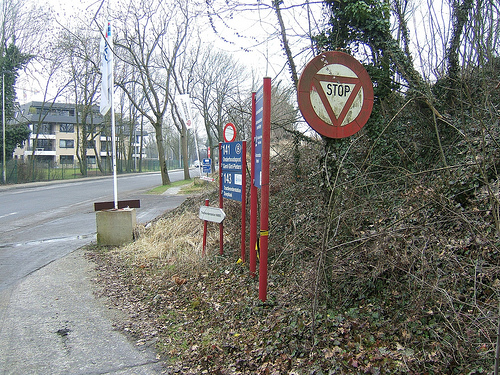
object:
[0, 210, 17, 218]
marking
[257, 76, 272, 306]
pole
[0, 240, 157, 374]
sidewalk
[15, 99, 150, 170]
building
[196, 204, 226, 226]
sign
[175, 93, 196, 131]
banner flag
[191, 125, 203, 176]
pole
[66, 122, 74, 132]
small window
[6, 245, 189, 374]
shoulder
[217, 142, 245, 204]
board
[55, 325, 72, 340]
mark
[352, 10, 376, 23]
green leaves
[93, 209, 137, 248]
cement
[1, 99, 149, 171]
building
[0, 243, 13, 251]
puddle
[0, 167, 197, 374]
pavement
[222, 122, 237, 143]
red sign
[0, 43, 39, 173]
trees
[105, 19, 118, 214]
flag pole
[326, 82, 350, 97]
word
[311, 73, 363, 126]
triangle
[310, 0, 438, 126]
tree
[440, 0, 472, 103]
tree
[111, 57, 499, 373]
hill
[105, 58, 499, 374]
grass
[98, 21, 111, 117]
flag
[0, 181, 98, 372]
curve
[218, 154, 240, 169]
text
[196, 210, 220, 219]
letters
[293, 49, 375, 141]
signs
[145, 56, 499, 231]
hillside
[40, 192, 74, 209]
portion